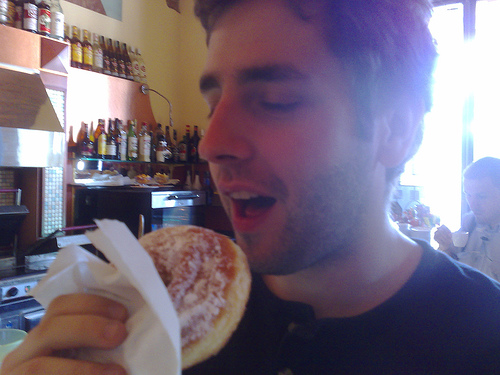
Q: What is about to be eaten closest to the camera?
A: Doughnut.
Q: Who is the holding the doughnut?
A: The closest guy.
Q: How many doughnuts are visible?
A: 1.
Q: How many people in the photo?
A: 2.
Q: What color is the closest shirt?
A: Black.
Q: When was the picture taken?
A: During the day.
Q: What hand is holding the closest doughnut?
A: Right.